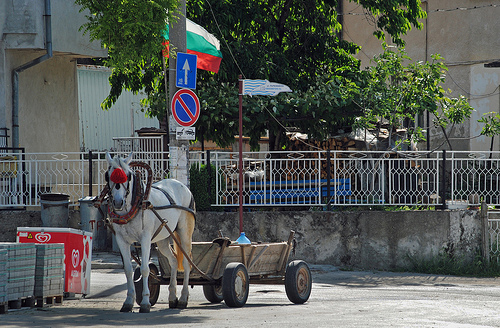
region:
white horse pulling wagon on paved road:
[92, 149, 317, 322]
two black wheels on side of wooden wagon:
[219, 253, 317, 308]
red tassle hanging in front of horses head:
[107, 162, 129, 187]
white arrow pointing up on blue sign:
[169, 47, 202, 88]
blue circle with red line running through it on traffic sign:
[165, 88, 202, 126]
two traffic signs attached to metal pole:
[164, 1, 202, 186]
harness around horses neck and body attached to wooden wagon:
[97, 149, 228, 280]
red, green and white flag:
[160, 6, 225, 86]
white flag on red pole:
[230, 67, 293, 241]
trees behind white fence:
[82, 2, 498, 158]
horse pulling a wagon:
[85, 149, 317, 313]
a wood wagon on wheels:
[127, 238, 318, 308]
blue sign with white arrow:
[172, 46, 201, 92]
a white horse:
[95, 149, 198, 311]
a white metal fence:
[3, 141, 498, 213]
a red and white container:
[15, 225, 95, 300]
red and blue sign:
[166, 87, 201, 127]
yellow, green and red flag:
[161, 0, 225, 83]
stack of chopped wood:
[270, 133, 404, 188]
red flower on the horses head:
[102, 148, 136, 213]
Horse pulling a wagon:
[94, 150, 314, 313]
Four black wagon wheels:
[130, 262, 313, 306]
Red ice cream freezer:
[15, 225, 94, 298]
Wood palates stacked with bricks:
[0, 240, 66, 309]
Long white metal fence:
[1, 147, 498, 209]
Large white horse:
[102, 150, 197, 311]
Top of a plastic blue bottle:
[235, 229, 252, 245]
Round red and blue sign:
[169, 88, 201, 129]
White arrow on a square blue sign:
[173, 48, 198, 90]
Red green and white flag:
[161, 5, 222, 74]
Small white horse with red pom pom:
[100, 146, 198, 312]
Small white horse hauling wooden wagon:
[97, 148, 194, 313]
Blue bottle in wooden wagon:
[232, 230, 255, 245]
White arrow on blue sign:
[179, 55, 192, 87]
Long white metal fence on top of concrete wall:
[0, 152, 499, 209]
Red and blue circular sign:
[170, 87, 200, 128]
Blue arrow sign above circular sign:
[175, 49, 197, 90]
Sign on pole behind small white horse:
[168, 88, 203, 128]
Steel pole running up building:
[7, 0, 54, 147]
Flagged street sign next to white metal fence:
[235, 70, 293, 235]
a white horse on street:
[100, 146, 192, 314]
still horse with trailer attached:
[102, 154, 314, 310]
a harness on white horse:
[100, 157, 213, 277]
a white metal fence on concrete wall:
[2, 147, 498, 217]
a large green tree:
[92, 0, 353, 207]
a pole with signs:
[164, 3, 196, 186]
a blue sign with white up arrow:
[172, 50, 199, 90]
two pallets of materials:
[0, 237, 65, 315]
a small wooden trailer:
[154, 235, 293, 275]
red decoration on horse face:
[104, 160, 126, 185]